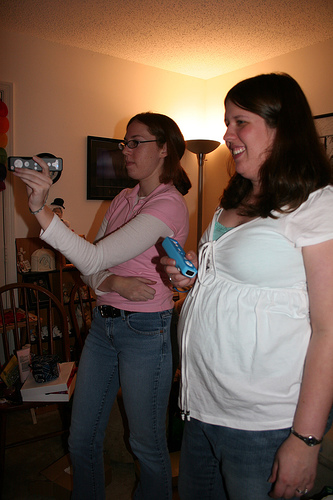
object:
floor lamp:
[182, 139, 220, 257]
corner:
[184, 74, 223, 266]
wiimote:
[6, 156, 63, 173]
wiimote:
[161, 237, 197, 279]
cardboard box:
[21, 361, 76, 404]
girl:
[17, 114, 191, 499]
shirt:
[95, 182, 189, 312]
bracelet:
[28, 198, 46, 216]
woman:
[160, 73, 332, 498]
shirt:
[176, 185, 332, 432]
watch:
[288, 428, 323, 447]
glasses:
[117, 135, 168, 149]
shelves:
[1, 239, 96, 417]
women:
[16, 111, 189, 497]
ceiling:
[0, 0, 332, 80]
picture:
[85, 135, 138, 201]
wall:
[0, 31, 332, 365]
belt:
[96, 304, 135, 319]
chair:
[1, 282, 70, 461]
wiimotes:
[160, 234, 195, 279]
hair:
[224, 73, 331, 220]